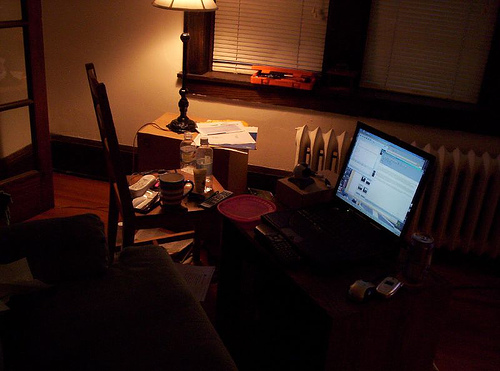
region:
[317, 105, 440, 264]
Monitor is on.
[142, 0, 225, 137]
The lamp is on.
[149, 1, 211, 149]
The lamp is on a table.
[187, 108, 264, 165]
The papers are white.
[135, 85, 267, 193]
The table is tan.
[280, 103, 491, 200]
The radiator is white.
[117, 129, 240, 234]
The chair is cluttered.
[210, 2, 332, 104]
The blinds are closed.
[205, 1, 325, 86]
The blinds are white.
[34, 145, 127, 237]
The floor is brown.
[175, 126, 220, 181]
water bottles on chair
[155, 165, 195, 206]
coffee mug on chair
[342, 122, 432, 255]
computer sitting on desk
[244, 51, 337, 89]
tools in window sill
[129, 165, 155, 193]
white cordless phone on chair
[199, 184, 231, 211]
black remote on chair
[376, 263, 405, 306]
cellphone sitting on desk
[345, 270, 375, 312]
silver mouse on desk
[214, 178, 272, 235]
red plastic plate on desk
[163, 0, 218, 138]
lamp sitting on cardboard box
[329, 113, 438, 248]
a flat screen computer monitor.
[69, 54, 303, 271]
a chair near a computer.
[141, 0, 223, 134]
a lamp on a desk.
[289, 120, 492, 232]
a heater for a room.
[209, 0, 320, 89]
mini blinds in a window.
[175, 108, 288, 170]
a pile of papers on a table.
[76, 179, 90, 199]
a section of a wooden floor.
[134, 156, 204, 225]
a cup with a drink.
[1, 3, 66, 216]
a large door in a room.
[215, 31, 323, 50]
a section of mini blinds.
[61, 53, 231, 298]
wooden straight back chair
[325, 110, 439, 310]
black computer monitor screen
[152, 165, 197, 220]
striped coffee mug sitting in chair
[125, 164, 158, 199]
white cordless phone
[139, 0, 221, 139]
side table lamp with white shade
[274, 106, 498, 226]
white radiator mounted to wall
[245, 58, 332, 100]
small plastic orange box sitting in window ceil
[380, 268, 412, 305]
silver flip cell phone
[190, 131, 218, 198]
clear water bottle sitting in seat to chair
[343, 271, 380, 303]
silver and black computer mouse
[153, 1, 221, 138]
lamp on left side of desk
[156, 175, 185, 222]
coffee cup on desk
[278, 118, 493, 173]
radiator along wall on right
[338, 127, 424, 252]
computer screen in use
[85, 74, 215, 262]
wooden chair on left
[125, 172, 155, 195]
telephone on chair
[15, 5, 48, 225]
door on left side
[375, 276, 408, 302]
cell phone next to computer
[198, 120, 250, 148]
papers on table under window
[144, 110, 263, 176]
table under window